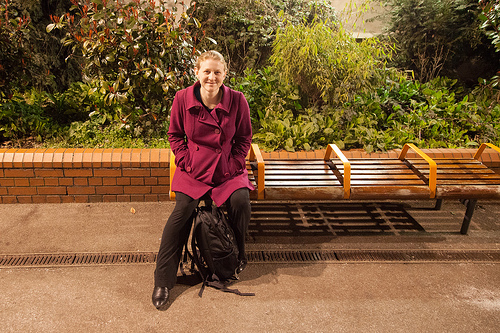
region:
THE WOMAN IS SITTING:
[144, 46, 257, 313]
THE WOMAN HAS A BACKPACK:
[182, 201, 249, 293]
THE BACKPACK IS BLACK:
[181, 186, 244, 305]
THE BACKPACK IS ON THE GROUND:
[173, 193, 251, 308]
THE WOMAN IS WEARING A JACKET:
[161, 81, 259, 228]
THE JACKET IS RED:
[153, 78, 268, 220]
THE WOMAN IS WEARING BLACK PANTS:
[143, 176, 250, 295]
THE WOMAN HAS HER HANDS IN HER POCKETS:
[161, 84, 268, 215]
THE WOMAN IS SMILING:
[192, 47, 232, 94]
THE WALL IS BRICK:
[1, 146, 497, 203]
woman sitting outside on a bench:
[147, 44, 260, 314]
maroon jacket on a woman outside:
[158, 84, 263, 209]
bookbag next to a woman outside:
[183, 203, 250, 295]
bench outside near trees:
[249, 139, 498, 215]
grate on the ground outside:
[2, 244, 157, 274]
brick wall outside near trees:
[7, 133, 164, 213]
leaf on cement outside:
[120, 200, 145, 220]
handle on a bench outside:
[317, 135, 362, 202]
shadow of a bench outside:
[250, 199, 439, 251]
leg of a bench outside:
[450, 188, 490, 245]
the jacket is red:
[162, 92, 252, 195]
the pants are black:
[168, 194, 187, 294]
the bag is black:
[188, 215, 257, 292]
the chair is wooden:
[298, 142, 482, 213]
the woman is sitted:
[131, 41, 287, 313]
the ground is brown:
[28, 210, 155, 331]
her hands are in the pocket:
[154, 103, 271, 203]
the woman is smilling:
[163, 53, 280, 294]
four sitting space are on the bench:
[180, 111, 494, 237]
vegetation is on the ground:
[42, 12, 471, 139]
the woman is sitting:
[144, 35, 269, 320]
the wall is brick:
[58, 162, 134, 198]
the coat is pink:
[156, 77, 278, 204]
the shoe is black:
[140, 280, 176, 309]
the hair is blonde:
[202, 51, 227, 64]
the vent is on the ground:
[16, 250, 139, 271]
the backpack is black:
[192, 202, 253, 294]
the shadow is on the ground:
[307, 207, 418, 237]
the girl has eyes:
[197, 63, 229, 78]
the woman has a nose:
[205, 69, 216, 83]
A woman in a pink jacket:
[151, 50, 249, 308]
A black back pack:
[184, 202, 253, 296]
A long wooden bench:
[170, 141, 499, 230]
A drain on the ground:
[2, 248, 499, 270]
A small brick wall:
[1, 147, 498, 202]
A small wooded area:
[0, 0, 497, 145]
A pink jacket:
[167, 79, 254, 204]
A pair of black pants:
[151, 188, 248, 288]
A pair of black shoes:
[152, 260, 247, 307]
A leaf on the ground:
[127, 204, 137, 215]